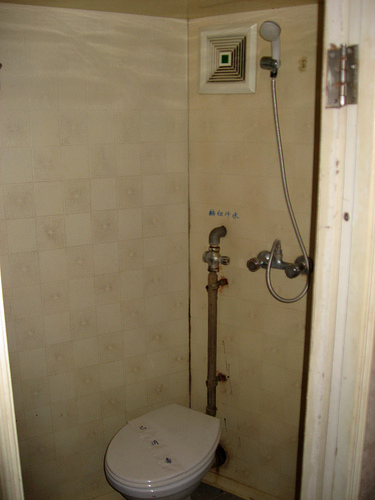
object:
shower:
[0, 4, 327, 498]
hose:
[265, 75, 311, 304]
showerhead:
[258, 19, 283, 73]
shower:
[241, 19, 317, 276]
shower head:
[259, 19, 281, 78]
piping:
[264, 78, 311, 308]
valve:
[284, 255, 315, 279]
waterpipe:
[203, 225, 229, 412]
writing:
[208, 208, 239, 220]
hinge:
[324, 43, 360, 108]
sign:
[139, 425, 173, 465]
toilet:
[104, 399, 223, 497]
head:
[201, 0, 346, 320]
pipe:
[197, 223, 230, 421]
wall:
[0, 0, 324, 499]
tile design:
[12, 193, 173, 291]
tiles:
[42, 257, 158, 344]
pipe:
[141, 197, 244, 325]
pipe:
[199, 223, 232, 413]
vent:
[198, 22, 258, 95]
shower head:
[257, 20, 282, 69]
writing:
[139, 425, 172, 464]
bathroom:
[1, 0, 373, 499]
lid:
[105, 402, 220, 483]